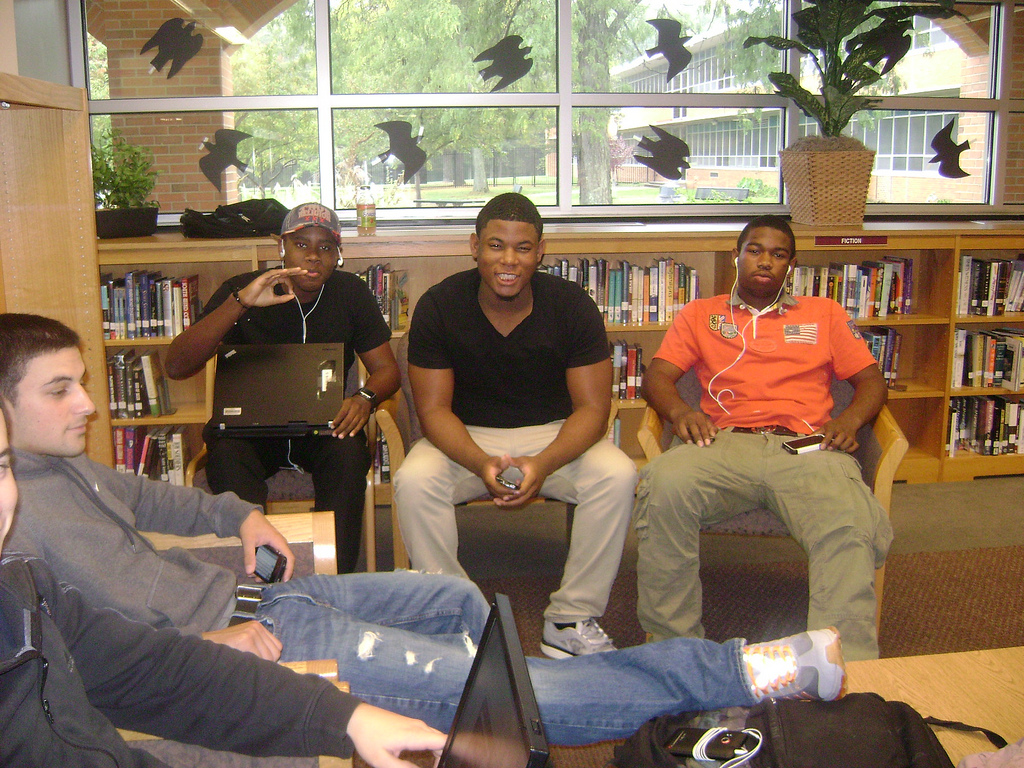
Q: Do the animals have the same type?
A: Yes, all the animals are birds.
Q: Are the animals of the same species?
A: Yes, all the animals are birds.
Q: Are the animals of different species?
A: No, all the animals are birds.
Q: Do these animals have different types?
A: No, all the animals are birds.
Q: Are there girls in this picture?
A: No, there are no girls.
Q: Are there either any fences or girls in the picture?
A: No, there are no girls or fences.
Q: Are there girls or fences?
A: No, there are no girls or fences.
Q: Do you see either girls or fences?
A: No, there are no girls or fences.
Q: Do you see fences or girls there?
A: No, there are no girls or fences.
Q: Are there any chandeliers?
A: No, there are no chandeliers.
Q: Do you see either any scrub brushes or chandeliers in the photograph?
A: No, there are no chandeliers or scrub brushes.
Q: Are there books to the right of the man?
A: Yes, there are books to the right of the man.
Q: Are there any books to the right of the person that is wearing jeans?
A: Yes, there are books to the right of the man.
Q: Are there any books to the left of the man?
A: No, the books are to the right of the man.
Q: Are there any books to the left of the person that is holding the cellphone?
A: No, the books are to the right of the man.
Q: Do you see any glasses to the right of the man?
A: No, there are books to the right of the man.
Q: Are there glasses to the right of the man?
A: No, there are books to the right of the man.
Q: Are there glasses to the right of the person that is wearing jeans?
A: No, there are books to the right of the man.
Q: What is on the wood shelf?
A: The books are on the shelf.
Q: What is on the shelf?
A: The books are on the shelf.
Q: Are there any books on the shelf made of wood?
A: Yes, there are books on the shelf.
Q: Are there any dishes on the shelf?
A: No, there are books on the shelf.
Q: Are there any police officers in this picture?
A: No, there are no police officers.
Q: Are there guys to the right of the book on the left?
A: Yes, there is a guy to the right of the book.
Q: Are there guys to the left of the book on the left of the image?
A: No, the guy is to the right of the book.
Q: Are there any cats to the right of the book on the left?
A: No, there is a guy to the right of the book.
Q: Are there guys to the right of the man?
A: Yes, there is a guy to the right of the man.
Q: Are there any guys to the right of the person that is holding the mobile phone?
A: Yes, there is a guy to the right of the man.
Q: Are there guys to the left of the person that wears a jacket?
A: No, the guy is to the right of the man.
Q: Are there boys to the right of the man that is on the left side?
A: No, there is a guy to the right of the man.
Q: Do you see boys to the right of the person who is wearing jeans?
A: No, there is a guy to the right of the man.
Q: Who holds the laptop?
A: The guy holds the laptop.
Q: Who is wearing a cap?
A: The guy is wearing a cap.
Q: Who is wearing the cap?
A: The guy is wearing a cap.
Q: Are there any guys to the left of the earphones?
A: Yes, there is a guy to the left of the earphones.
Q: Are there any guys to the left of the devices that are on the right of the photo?
A: Yes, there is a guy to the left of the earphones.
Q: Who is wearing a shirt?
A: The guy is wearing a shirt.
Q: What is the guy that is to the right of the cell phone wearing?
A: The guy is wearing a shirt.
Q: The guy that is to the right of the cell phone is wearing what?
A: The guy is wearing a shirt.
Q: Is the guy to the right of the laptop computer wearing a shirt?
A: Yes, the guy is wearing a shirt.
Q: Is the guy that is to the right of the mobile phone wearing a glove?
A: No, the guy is wearing a shirt.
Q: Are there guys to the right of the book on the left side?
A: Yes, there is a guy to the right of the book.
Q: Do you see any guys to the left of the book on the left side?
A: No, the guy is to the right of the book.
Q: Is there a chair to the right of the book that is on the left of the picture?
A: No, there is a guy to the right of the book.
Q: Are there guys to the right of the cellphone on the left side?
A: Yes, there is a guy to the right of the mobile phone.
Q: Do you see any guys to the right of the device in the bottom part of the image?
A: Yes, there is a guy to the right of the mobile phone.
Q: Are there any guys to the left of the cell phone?
A: No, the guy is to the right of the cell phone.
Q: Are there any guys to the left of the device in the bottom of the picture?
A: No, the guy is to the right of the cell phone.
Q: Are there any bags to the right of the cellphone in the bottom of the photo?
A: No, there is a guy to the right of the cellphone.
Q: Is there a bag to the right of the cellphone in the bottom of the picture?
A: No, there is a guy to the right of the cellphone.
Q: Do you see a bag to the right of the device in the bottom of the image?
A: No, there is a guy to the right of the cellphone.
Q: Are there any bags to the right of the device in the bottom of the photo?
A: No, there is a guy to the right of the cellphone.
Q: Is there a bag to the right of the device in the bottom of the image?
A: No, there is a guy to the right of the cellphone.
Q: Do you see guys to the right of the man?
A: Yes, there is a guy to the right of the man.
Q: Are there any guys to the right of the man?
A: Yes, there is a guy to the right of the man.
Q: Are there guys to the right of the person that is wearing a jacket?
A: Yes, there is a guy to the right of the man.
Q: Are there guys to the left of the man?
A: No, the guy is to the right of the man.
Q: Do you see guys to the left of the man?
A: No, the guy is to the right of the man.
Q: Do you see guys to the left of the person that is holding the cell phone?
A: No, the guy is to the right of the man.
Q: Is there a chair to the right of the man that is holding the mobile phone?
A: No, there is a guy to the right of the man.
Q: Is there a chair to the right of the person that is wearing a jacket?
A: No, there is a guy to the right of the man.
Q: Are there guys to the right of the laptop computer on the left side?
A: Yes, there is a guy to the right of the laptop.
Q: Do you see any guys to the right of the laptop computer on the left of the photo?
A: Yes, there is a guy to the right of the laptop.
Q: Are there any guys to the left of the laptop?
A: No, the guy is to the right of the laptop.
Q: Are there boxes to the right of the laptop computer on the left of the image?
A: No, there is a guy to the right of the laptop.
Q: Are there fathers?
A: No, there are no fathers.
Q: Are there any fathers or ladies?
A: No, there are no fathers or ladies.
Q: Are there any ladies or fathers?
A: No, there are no fathers or ladies.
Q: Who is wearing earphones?
A: The guy is wearing earphones.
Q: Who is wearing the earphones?
A: The guy is wearing earphones.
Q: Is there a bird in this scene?
A: Yes, there is a bird.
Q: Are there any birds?
A: Yes, there is a bird.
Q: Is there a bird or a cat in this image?
A: Yes, there is a bird.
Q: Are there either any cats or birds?
A: Yes, there is a bird.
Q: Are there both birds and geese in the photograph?
A: No, there is a bird but no geese.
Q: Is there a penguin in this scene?
A: No, there are no penguins.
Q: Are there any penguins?
A: No, there are no penguins.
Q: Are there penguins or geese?
A: No, there are no penguins or geese.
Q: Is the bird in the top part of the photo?
A: Yes, the bird is in the top of the image.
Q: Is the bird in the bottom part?
A: No, the bird is in the top of the image.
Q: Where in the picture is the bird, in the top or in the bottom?
A: The bird is in the top of the image.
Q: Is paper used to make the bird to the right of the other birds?
A: Yes, the bird is made of paper.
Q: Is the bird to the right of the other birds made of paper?
A: Yes, the bird is made of paper.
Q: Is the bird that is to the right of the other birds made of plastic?
A: No, the bird is made of paper.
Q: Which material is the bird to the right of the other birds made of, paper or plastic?
A: The bird is made of paper.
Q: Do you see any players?
A: No, there are no players.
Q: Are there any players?
A: No, there are no players.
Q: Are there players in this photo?
A: No, there are no players.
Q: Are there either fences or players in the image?
A: No, there are no players or fences.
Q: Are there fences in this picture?
A: No, there are no fences.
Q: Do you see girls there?
A: No, there are no girls.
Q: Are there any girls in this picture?
A: No, there are no girls.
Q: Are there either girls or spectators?
A: No, there are no girls or spectators.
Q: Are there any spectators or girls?
A: No, there are no girls or spectators.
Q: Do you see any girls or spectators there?
A: No, there are no girls or spectators.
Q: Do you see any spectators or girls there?
A: No, there are no girls or spectators.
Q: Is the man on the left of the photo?
A: Yes, the man is on the left of the image.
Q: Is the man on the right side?
A: No, the man is on the left of the image.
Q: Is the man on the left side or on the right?
A: The man is on the left of the image.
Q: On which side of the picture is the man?
A: The man is on the left of the image.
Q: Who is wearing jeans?
A: The man is wearing jeans.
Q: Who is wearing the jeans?
A: The man is wearing jeans.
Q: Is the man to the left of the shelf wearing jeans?
A: Yes, the man is wearing jeans.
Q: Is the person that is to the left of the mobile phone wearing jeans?
A: Yes, the man is wearing jeans.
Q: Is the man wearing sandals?
A: No, the man is wearing jeans.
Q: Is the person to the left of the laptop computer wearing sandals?
A: No, the man is wearing jeans.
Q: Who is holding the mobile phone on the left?
A: The man is holding the cell phone.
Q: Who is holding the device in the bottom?
A: The man is holding the cell phone.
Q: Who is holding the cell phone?
A: The man is holding the cell phone.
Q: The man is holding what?
A: The man is holding the cellphone.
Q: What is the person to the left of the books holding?
A: The man is holding the cellphone.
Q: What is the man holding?
A: The man is holding the cellphone.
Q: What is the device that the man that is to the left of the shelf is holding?
A: The device is a cell phone.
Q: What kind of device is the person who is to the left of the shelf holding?
A: The man is holding the cell phone.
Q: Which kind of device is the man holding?
A: The man is holding the cell phone.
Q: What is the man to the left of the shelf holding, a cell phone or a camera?
A: The man is holding a cell phone.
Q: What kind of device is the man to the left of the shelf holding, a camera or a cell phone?
A: The man is holding a cell phone.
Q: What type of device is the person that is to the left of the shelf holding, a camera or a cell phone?
A: The man is holding a cell phone.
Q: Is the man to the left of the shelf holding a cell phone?
A: Yes, the man is holding a cell phone.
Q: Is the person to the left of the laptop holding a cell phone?
A: Yes, the man is holding a cell phone.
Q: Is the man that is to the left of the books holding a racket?
A: No, the man is holding a cell phone.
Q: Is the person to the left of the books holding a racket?
A: No, the man is holding a cell phone.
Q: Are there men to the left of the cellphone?
A: Yes, there is a man to the left of the cellphone.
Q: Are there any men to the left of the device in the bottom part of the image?
A: Yes, there is a man to the left of the cellphone.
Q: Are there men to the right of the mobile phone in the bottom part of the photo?
A: No, the man is to the left of the mobile phone.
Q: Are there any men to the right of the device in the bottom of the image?
A: No, the man is to the left of the mobile phone.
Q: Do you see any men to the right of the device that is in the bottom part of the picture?
A: No, the man is to the left of the mobile phone.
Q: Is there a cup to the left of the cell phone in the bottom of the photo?
A: No, there is a man to the left of the cell phone.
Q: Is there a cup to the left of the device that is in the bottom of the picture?
A: No, there is a man to the left of the cell phone.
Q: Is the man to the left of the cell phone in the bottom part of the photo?
A: Yes, the man is to the left of the cell phone.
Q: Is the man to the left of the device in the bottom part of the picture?
A: Yes, the man is to the left of the cell phone.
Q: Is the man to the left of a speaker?
A: No, the man is to the left of the cell phone.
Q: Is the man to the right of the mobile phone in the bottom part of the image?
A: No, the man is to the left of the cellphone.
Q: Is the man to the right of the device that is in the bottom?
A: No, the man is to the left of the cellphone.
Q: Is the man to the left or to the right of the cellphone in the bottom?
A: The man is to the left of the cell phone.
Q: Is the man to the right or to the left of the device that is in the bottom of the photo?
A: The man is to the left of the cell phone.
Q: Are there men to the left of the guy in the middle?
A: Yes, there is a man to the left of the guy.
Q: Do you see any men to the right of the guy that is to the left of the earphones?
A: No, the man is to the left of the guy.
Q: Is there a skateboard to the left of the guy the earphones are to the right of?
A: No, there is a man to the left of the guy.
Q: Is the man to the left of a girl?
A: No, the man is to the left of a guy.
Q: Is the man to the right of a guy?
A: No, the man is to the left of a guy.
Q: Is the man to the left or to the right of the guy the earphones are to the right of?
A: The man is to the left of the guy.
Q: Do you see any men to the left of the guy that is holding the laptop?
A: Yes, there is a man to the left of the guy.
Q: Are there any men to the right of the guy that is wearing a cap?
A: No, the man is to the left of the guy.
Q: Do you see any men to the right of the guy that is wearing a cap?
A: No, the man is to the left of the guy.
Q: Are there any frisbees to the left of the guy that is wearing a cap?
A: No, there is a man to the left of the guy.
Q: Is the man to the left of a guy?
A: Yes, the man is to the left of a guy.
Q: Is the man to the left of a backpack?
A: No, the man is to the left of a guy.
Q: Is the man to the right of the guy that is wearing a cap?
A: No, the man is to the left of the guy.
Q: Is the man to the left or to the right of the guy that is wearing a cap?
A: The man is to the left of the guy.